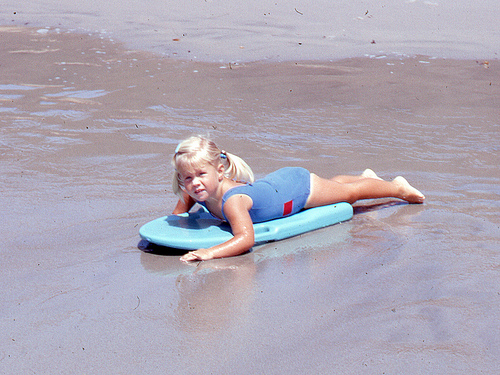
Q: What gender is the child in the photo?
A: Female.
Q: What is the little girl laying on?
A: Boogie board.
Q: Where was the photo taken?
A: At beach.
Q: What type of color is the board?
A: Blue.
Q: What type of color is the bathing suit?
A: Blue.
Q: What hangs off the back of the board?
A: Legs.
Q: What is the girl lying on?
A: A floatie.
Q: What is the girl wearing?
A: Bathing suit.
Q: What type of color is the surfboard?
A: Blue.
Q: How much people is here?
A: 1.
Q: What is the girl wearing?
A: One piece suit.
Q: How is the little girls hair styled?
A: In pigtails.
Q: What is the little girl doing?
A: Laying on a boogie board.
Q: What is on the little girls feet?
A: Nothing.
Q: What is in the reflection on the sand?
A: The little girl.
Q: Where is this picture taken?
A: The beach.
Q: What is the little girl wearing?
A: Bathing suit.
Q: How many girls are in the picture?
A: One.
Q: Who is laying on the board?
A: Little Girl.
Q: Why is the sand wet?
A: Waves.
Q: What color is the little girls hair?
A: Blonde.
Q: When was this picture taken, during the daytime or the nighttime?
A: Daytime.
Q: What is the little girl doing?
A: Lying down.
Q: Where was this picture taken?
A: Beach.